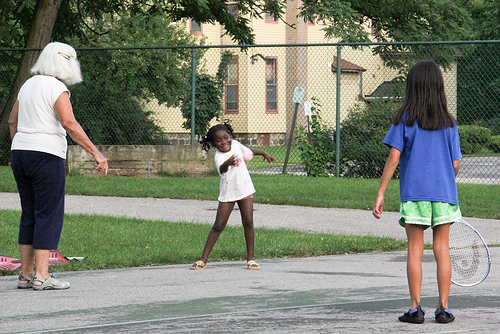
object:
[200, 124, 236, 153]
head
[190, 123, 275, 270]
girl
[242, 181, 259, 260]
leg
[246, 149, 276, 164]
arm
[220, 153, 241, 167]
hand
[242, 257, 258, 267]
foot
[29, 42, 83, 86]
head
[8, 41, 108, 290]
woman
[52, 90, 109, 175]
arm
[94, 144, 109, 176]
hand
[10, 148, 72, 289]
leg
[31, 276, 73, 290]
foot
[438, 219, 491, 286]
racket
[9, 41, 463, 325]
people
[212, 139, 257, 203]
shirt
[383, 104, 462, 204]
shirt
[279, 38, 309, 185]
post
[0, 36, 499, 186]
fence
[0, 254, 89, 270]
equipment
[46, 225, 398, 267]
grass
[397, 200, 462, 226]
shorts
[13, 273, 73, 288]
shoes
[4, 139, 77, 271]
poants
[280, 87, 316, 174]
sign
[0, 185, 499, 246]
sidewalk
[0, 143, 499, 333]
ground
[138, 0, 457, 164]
building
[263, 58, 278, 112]
window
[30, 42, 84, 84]
hair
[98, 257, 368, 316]
asphault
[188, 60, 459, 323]
children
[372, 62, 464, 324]
girl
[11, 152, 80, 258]
pants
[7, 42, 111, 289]
lady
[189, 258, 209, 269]
sandals